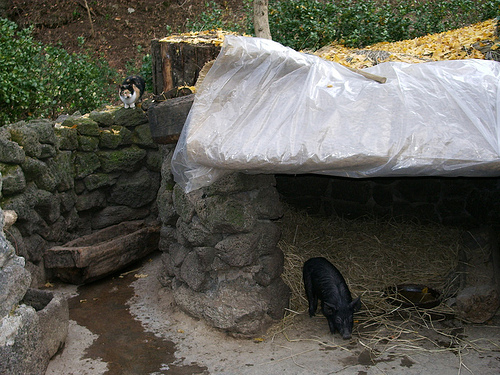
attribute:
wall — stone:
[0, 98, 165, 373]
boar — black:
[301, 269, 419, 357]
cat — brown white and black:
[103, 67, 167, 117]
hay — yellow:
[283, 201, 488, 351]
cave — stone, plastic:
[150, 43, 499, 350]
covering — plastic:
[153, 37, 498, 193]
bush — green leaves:
[0, 18, 114, 103]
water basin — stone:
[41, 220, 157, 277]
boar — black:
[286, 260, 381, 364]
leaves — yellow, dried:
[344, 28, 499, 78]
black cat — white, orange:
[84, 74, 190, 134]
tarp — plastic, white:
[173, 37, 494, 179]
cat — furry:
[117, 75, 145, 109]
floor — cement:
[272, 343, 408, 372]